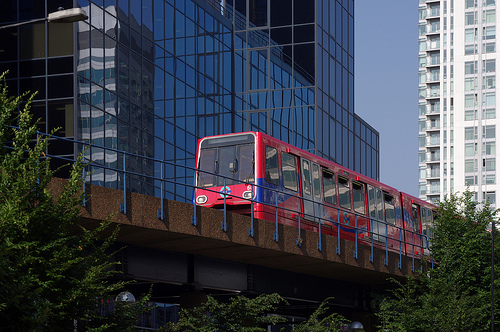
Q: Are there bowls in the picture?
A: No, there are no bowls.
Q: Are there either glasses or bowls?
A: No, there are no bowls or glasses.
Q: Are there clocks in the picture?
A: No, there are no clocks.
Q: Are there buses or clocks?
A: No, there are no clocks or buses.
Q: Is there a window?
A: Yes, there are windows.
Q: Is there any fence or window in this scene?
A: Yes, there are windows.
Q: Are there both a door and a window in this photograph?
A: Yes, there are both a window and a door.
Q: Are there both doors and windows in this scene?
A: Yes, there are both windows and a door.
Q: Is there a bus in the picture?
A: No, there are no buses.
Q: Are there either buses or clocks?
A: No, there are no buses or clocks.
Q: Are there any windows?
A: Yes, there are windows.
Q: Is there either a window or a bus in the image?
A: Yes, there are windows.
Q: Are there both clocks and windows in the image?
A: No, there are windows but no clocks.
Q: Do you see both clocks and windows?
A: No, there are windows but no clocks.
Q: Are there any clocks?
A: No, there are no clocks.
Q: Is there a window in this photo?
A: Yes, there are windows.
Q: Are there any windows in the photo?
A: Yes, there are windows.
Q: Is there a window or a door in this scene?
A: Yes, there are windows.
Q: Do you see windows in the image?
A: Yes, there are windows.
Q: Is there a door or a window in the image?
A: Yes, there are windows.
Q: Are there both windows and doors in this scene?
A: Yes, there are both windows and a door.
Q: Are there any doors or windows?
A: Yes, there are windows.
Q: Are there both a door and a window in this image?
A: Yes, there are both a window and a door.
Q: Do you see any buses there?
A: No, there are no buses.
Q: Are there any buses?
A: No, there are no buses.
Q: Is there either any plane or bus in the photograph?
A: No, there are no buses or airplanes.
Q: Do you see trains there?
A: Yes, there is a train.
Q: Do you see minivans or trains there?
A: Yes, there is a train.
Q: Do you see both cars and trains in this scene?
A: Yes, there are both a train and a car.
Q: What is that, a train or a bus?
A: That is a train.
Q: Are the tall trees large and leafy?
A: Yes, the trees are large and leafy.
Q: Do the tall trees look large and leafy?
A: Yes, the trees are large and leafy.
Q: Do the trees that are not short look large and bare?
A: No, the trees are large but leafy.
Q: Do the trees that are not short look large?
A: Yes, the trees are large.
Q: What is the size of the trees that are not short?
A: The trees are large.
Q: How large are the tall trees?
A: The trees are large.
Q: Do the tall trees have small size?
A: No, the trees are large.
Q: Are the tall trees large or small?
A: The trees are large.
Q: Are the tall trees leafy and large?
A: Yes, the trees are leafy and large.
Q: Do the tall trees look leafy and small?
A: No, the trees are leafy but large.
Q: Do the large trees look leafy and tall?
A: Yes, the trees are leafy and tall.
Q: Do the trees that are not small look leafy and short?
A: No, the trees are leafy but tall.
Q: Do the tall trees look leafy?
A: Yes, the trees are leafy.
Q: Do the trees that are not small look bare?
A: No, the trees are leafy.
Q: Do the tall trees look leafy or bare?
A: The trees are leafy.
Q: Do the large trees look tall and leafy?
A: Yes, the trees are tall and leafy.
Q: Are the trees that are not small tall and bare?
A: No, the trees are tall but leafy.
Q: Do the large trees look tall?
A: Yes, the trees are tall.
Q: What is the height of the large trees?
A: The trees are tall.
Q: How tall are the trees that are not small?
A: The trees are tall.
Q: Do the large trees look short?
A: No, the trees are tall.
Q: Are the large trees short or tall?
A: The trees are tall.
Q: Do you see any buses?
A: No, there are no buses.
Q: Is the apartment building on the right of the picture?
A: Yes, the apartment building is on the right of the image.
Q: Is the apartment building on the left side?
A: No, the apartment building is on the right of the image.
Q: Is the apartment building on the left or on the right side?
A: The apartment building is on the right of the image.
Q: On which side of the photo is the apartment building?
A: The apartment building is on the right of the image.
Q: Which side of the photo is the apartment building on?
A: The apartment building is on the right of the image.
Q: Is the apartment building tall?
A: Yes, the apartment building is tall.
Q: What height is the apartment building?
A: The apartment building is tall.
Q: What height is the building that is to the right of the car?
A: The apartment building is tall.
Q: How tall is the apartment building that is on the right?
A: The apartment building is tall.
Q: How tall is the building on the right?
A: The apartment building is tall.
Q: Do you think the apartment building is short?
A: No, the apartment building is tall.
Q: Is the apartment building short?
A: No, the apartment building is tall.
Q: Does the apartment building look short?
A: No, the apartment building is tall.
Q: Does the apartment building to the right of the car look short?
A: No, the apartment building is tall.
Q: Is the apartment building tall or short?
A: The apartment building is tall.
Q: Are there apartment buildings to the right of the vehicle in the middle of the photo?
A: Yes, there is an apartment building to the right of the car.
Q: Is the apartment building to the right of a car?
A: Yes, the apartment building is to the right of a car.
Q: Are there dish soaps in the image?
A: No, there are no dish soaps.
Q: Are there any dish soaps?
A: No, there are no dish soaps.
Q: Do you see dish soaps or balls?
A: No, there are no dish soaps or balls.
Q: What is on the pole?
A: The lamp post is on the pole.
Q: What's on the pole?
A: The lamp post is on the pole.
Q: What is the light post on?
A: The light post is on the pole.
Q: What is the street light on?
A: The light post is on the pole.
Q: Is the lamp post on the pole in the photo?
A: Yes, the lamp post is on the pole.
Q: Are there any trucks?
A: No, there are no trucks.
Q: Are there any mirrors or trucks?
A: No, there are no trucks or mirrors.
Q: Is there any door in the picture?
A: Yes, there are doors.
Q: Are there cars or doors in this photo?
A: Yes, there are doors.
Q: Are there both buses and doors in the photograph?
A: No, there are doors but no buses.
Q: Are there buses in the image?
A: No, there are no buses.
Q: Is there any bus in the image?
A: No, there are no buses.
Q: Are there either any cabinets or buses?
A: No, there are no buses or cabinets.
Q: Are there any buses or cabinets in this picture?
A: No, there are no buses or cabinets.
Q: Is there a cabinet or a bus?
A: No, there are no buses or cabinets.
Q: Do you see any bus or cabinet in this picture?
A: No, there are no buses or cabinets.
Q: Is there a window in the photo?
A: Yes, there are windows.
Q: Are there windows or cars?
A: Yes, there are windows.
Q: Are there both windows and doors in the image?
A: Yes, there are both windows and a door.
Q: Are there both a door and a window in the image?
A: Yes, there are both a window and a door.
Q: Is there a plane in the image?
A: No, there are no airplanes.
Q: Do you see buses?
A: No, there are no buses.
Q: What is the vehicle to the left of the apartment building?
A: The vehicle is a car.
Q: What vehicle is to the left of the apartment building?
A: The vehicle is a car.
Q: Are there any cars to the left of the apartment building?
A: Yes, there is a car to the left of the apartment building.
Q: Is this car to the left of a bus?
A: No, the car is to the left of the apartment building.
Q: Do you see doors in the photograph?
A: Yes, there are doors.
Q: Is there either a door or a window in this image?
A: Yes, there are doors.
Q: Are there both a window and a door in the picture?
A: Yes, there are both a door and a window.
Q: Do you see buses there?
A: No, there are no buses.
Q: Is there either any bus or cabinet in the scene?
A: No, there are no buses or cabinets.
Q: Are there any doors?
A: Yes, there are doors.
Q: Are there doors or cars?
A: Yes, there are doors.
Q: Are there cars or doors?
A: Yes, there are doors.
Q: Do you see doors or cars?
A: Yes, there are doors.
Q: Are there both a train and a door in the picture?
A: Yes, there are both a door and a train.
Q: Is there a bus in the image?
A: No, there are no buses.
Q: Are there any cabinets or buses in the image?
A: No, there are no buses or cabinets.